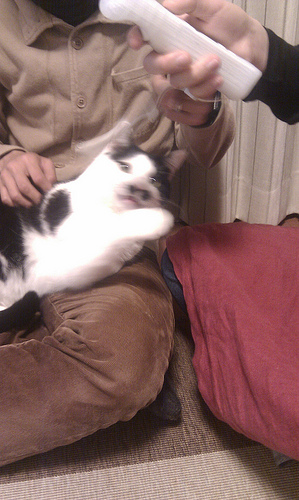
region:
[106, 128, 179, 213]
the head of a cat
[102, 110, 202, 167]
the ears of a cat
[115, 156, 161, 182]
the eyes of a cat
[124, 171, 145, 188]
the nose of a cat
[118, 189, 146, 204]
the mouth of a cat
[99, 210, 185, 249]
the paw of a cat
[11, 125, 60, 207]
the hand of a person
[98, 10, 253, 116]
a white wii remote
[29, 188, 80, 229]
the spot on a cat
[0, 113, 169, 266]
cat in the lap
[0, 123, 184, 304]
cat in the lap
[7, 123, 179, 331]
cat in the lap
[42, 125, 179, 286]
cat in the lap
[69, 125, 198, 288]
cat in the lap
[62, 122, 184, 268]
cat in the lap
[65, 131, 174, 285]
cat in the lap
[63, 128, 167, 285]
cat in the lap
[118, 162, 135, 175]
The left eye of the cat.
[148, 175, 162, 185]
The right eye of the cat.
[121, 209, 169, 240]
The left paw of the cat.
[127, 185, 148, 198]
The nose of the cat.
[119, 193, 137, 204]
The mouth of the cat.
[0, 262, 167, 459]
The brown pants the man is wearing.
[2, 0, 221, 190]
The brown shirt the man is wearing.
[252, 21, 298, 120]
The black sweater the person on the right is wearing.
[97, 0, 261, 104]
The Wii remote in the person's hand.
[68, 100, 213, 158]
The strap of the Wii remote.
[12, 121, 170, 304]
This is a cat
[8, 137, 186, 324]
The cat is on someone's lap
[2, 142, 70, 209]
The person's right hand is on the cat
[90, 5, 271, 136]
The people are holding Wii controllers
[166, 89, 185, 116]
A ring on his left hand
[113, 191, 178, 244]
Cat batting at something with its paw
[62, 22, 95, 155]
Brown shirt buttons are buttoned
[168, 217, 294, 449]
Red shirt on person's lap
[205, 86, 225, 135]
Watch on his left wrist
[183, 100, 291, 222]
Curtain behind the two people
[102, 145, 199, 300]
a cat in the lap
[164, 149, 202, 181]
an ear on the cat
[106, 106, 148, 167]
an ear on the cat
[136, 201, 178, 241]
a paw on the cat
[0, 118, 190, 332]
black and white cat on person's lap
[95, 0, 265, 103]
white remote control in person's hand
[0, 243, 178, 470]
pair of brown long pants on person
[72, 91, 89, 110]
tan button on tan shirt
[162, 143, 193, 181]
one pink cat ear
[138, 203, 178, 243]
one white cat paw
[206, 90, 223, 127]
silver face of black watch on wrist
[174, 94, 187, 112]
gold ring on finger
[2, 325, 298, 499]
tan seat with ridged texture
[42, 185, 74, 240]
black spot on cat's fur